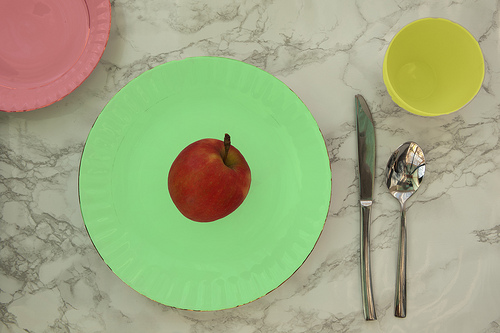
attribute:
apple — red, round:
[182, 137, 248, 201]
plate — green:
[226, 69, 309, 137]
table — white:
[284, 18, 343, 67]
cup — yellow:
[392, 31, 478, 109]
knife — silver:
[337, 92, 390, 304]